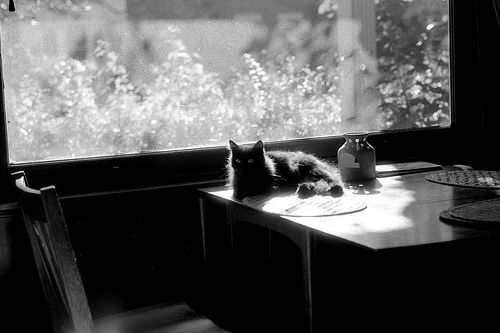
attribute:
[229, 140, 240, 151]
ear — pointy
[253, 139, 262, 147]
ear — pointy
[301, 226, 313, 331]
table leg — wooden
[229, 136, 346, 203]
cat — furry, black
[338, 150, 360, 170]
label — white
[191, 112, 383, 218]
cat — laying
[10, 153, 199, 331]
chair — wood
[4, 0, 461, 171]
window — large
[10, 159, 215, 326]
chair — wood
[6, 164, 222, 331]
dining chair — wood